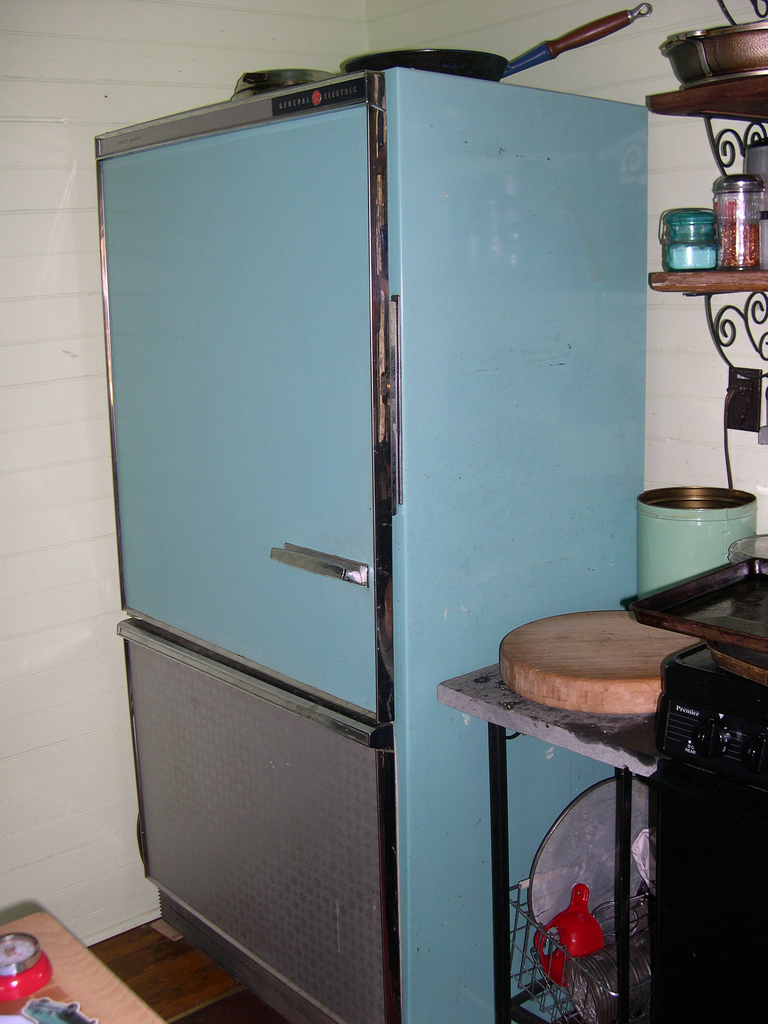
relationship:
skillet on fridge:
[337, 1, 650, 83] [91, 62, 651, 1023]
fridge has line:
[91, 62, 651, 1023] [368, 719, 415, 1015]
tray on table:
[522, 599, 687, 696] [436, 649, 655, 1021]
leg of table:
[482, 719, 525, 1022] [424, 664, 700, 1017]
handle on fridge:
[255, 534, 372, 592] [44, 50, 667, 1014]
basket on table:
[509, 866, 570, 1020] [427, 652, 672, 1009]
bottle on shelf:
[676, 200, 713, 270] [644, 263, 738, 316]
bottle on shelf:
[714, 174, 759, 266] [638, 265, 738, 301]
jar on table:
[647, 471, 760, 592] [427, 652, 672, 1009]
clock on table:
[1, 911, 64, 996] [0, 903, 175, 1021]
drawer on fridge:
[108, 614, 402, 1014] [44, 50, 667, 1014]